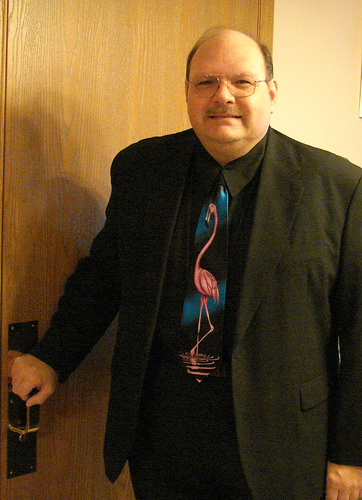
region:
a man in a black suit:
[10, 25, 360, 498]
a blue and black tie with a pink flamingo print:
[176, 174, 229, 382]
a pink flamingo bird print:
[188, 201, 220, 363]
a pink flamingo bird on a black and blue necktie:
[186, 202, 220, 360]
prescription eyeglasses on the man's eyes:
[186, 72, 266, 99]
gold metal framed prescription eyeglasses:
[186, 72, 266, 99]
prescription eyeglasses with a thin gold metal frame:
[186, 72, 267, 98]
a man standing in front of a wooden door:
[0, 1, 360, 498]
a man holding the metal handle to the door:
[2, 1, 359, 497]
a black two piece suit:
[25, 125, 360, 498]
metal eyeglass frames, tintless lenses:
[180, 71, 272, 100]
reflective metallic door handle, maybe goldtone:
[5, 315, 46, 483]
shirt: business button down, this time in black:
[147, 127, 283, 423]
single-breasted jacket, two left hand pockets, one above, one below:
[267, 219, 345, 455]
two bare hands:
[6, 352, 361, 497]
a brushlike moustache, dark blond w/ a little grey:
[196, 100, 247, 118]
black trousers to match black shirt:
[113, 387, 305, 499]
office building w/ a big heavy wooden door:
[1, 0, 361, 498]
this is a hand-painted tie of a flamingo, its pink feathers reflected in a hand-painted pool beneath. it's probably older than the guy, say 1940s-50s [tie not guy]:
[170, 171, 232, 389]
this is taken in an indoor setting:
[19, 12, 331, 470]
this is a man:
[82, 90, 329, 393]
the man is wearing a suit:
[80, 119, 330, 265]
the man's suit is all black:
[174, 164, 272, 462]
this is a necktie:
[184, 152, 296, 440]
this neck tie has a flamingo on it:
[172, 172, 252, 390]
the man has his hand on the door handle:
[10, 320, 52, 419]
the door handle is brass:
[15, 409, 90, 476]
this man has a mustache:
[146, 46, 288, 144]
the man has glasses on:
[172, 59, 318, 140]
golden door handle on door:
[8, 327, 43, 478]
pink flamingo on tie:
[181, 182, 234, 387]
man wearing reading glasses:
[183, 59, 267, 104]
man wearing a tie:
[154, 161, 241, 401]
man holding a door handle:
[3, 317, 58, 484]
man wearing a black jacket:
[34, 104, 360, 498]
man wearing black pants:
[124, 398, 271, 497]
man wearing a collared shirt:
[189, 139, 267, 201]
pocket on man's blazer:
[295, 373, 340, 425]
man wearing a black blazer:
[51, 115, 359, 495]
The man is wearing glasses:
[177, 18, 275, 158]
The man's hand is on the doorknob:
[1, 326, 56, 438]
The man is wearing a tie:
[174, 161, 235, 391]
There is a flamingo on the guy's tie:
[173, 187, 235, 392]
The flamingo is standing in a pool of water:
[170, 336, 224, 381]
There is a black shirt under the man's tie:
[140, 149, 263, 395]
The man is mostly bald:
[178, 27, 271, 79]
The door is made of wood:
[55, 408, 100, 495]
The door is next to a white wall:
[287, 6, 350, 125]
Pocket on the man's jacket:
[288, 362, 340, 465]